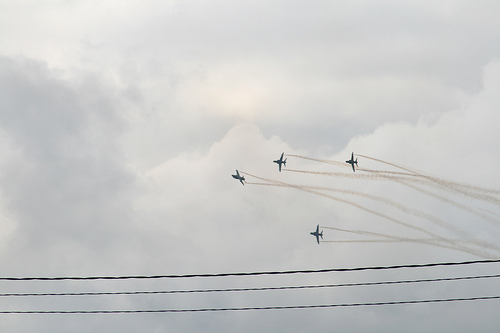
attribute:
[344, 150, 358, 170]
jet — flying 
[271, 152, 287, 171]
jet — flying 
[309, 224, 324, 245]
jet — flying 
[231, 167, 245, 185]
jet — flying 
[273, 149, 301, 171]
planes — Flying 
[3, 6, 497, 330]
sky — white , cloudy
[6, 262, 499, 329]
wires — black, electrical